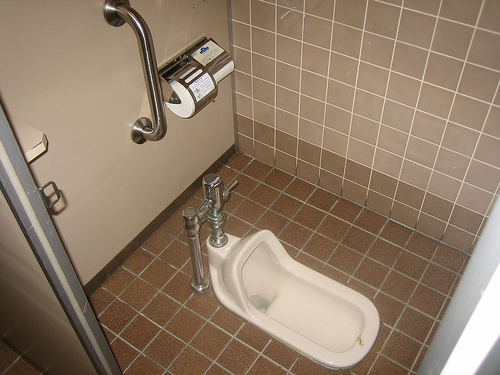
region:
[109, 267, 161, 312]
tiles on a restroom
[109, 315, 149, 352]
tiles on a restroom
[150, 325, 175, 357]
tiles on a restroom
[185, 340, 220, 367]
tiles on a restroom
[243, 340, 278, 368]
tiles on a restroom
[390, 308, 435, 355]
tiles on a restroom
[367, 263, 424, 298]
tiles on a restroom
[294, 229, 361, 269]
tiles on a restroom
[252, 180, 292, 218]
tiles on a restroom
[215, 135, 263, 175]
tiles on a restroom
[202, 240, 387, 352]
a urinal on the floor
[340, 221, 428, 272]
a section of tile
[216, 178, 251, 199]
the flushing handle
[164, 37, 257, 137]
toilet paper dispenser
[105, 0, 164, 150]
the handicap bar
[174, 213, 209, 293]
a water pipe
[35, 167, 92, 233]
the latch to lock the stall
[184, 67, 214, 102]
a sticker on the toilet paper dispenser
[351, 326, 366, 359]
a stain on the toilet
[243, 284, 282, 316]
the water reservoir for flushing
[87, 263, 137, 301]
tile of a restroom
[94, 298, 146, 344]
tile of a restroom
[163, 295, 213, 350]
tile of a restroom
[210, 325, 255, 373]
tile of a restroom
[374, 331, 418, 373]
tile of a restroom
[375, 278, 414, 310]
tile of a restroom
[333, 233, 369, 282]
tile of a restroom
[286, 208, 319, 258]
tile of a restroom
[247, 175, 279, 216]
tile of a restroom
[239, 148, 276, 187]
tile of a restroom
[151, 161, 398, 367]
A squat toilet bowl room.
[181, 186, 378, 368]
a traditional japanese toilet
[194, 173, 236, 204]
the flusher of a toilet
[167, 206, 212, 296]
the pipe of a toilet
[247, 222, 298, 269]
the rim of a toilet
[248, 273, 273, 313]
the hole in a toilet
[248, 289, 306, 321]
the water in a toilet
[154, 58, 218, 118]
a roll of white toilet paper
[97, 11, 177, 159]
the handle in a bathroom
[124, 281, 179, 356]
the tile floor in a bathroom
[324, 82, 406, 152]
the tiles on the wall